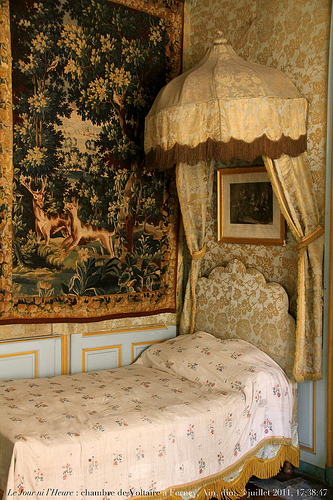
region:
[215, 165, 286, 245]
silver framed photo on the wall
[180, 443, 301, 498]
yellow fringe on bed skirt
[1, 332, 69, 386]
white wall section with yellow edge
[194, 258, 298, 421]
cloth yellow headboard with flowers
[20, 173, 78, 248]
picture of buck on tapestry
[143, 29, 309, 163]
decorative feature above bed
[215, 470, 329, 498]
small section of hardwood floor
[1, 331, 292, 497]
bed spread with small flowers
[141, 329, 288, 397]
pillows under the bed spread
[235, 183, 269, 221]
people in photo above bed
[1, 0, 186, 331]
hand-embroidered tapestry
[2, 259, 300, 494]
single bed with silken headboard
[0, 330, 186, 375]
yellow and white wainscoating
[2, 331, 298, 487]
cream-colored floral blanket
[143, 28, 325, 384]
heavy gold tapestry canopy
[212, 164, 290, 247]
small, gold-framed print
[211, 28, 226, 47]
decorative topper on canopy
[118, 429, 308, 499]
mustard yellow tassles on bed skirt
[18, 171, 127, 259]
embroidery of two deer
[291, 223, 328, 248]
tassled tie-back on canopy curtains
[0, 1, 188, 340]
a rug hanging on the wall by a bed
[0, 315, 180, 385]
a yellow and white wall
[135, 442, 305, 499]
gold fringe on a bed skirt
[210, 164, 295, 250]
a picture above a bed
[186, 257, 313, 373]
a gold and white flowered headboard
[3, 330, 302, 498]
a flowered bed spread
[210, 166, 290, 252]
a gold frame on a picture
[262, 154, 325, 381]
golden floral curtains by a bed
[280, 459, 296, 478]
the wooden foot of a bed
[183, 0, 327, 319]
gold floral wallpaper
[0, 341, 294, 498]
bed with floral bedspread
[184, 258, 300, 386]
gold floral pattern headboard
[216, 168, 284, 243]
gold framed photograph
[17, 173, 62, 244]
buck deer on wallhanging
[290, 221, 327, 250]
gold tiebacks for fabric curtains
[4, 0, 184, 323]
large deer themed wallhanging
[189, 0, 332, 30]
gold and white floral fabric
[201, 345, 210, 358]
red and blue flowers on bedspread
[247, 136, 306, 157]
decorative brown tassles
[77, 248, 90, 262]
white and red flower on wallhanging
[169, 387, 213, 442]
a bed is visible.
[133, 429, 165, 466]
a bed is visible.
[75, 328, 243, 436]
a bed is visible.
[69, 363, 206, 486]
a bed is visible.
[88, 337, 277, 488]
a bed is visible.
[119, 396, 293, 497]
a bed is visible.